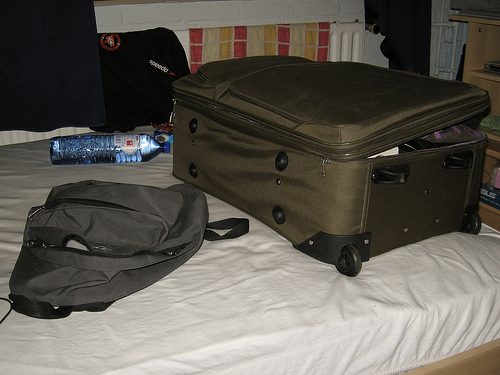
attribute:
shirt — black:
[90, 27, 190, 131]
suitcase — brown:
[170, 52, 490, 276]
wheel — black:
[323, 235, 391, 289]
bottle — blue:
[48, 130, 170, 166]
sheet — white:
[0, 124, 485, 372]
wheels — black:
[334, 241, 364, 279]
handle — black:
[9, 290, 124, 320]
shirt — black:
[74, 27, 194, 134]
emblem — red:
[97, 32, 123, 54]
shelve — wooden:
[443, 12, 485, 223]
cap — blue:
[161, 140, 171, 154]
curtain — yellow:
[169, 13, 331, 107]